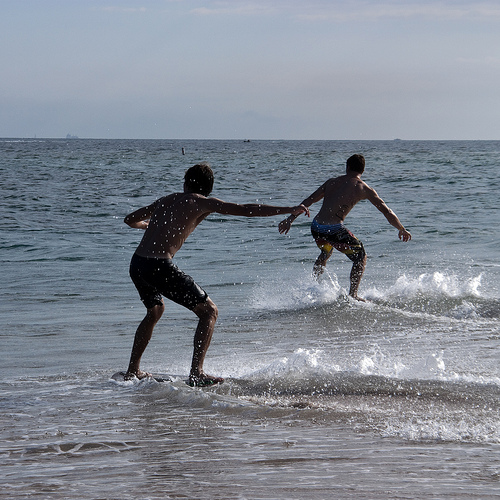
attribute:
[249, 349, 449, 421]
waves — nice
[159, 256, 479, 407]
waves — good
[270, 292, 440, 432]
waves — small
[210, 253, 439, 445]
waves — beautiful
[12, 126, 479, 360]
water — calm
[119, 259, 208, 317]
shorts — black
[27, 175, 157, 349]
water — blue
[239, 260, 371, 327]
water splash — white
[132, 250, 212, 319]
shorts — black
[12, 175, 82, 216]
line — dark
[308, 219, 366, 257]
shorts — black, blue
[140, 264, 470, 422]
waves — ocean, calm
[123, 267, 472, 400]
waves — nice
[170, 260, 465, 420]
waves — water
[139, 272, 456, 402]
waves — awesome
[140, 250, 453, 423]
waves — some